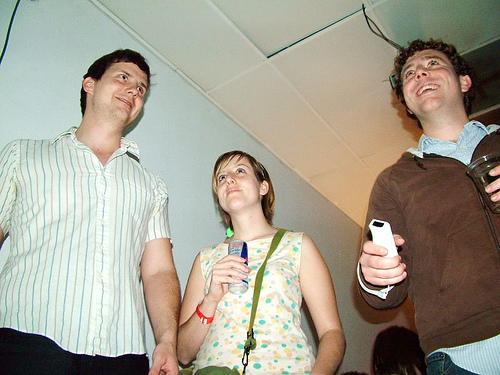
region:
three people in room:
[34, 15, 468, 365]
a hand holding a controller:
[359, 245, 411, 286]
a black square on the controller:
[374, 215, 381, 225]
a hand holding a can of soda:
[211, 257, 248, 285]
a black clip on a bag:
[241, 345, 251, 365]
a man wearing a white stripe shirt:
[11, 22, 167, 359]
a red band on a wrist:
[194, 306, 219, 330]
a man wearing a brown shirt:
[359, 45, 498, 364]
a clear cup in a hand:
[469, 142, 499, 209]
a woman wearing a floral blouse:
[199, 143, 328, 373]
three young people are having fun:
[2, 6, 497, 372]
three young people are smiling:
[6, 21, 489, 277]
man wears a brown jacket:
[349, 23, 499, 365]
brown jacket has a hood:
[352, 123, 499, 357]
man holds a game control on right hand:
[337, 30, 499, 352]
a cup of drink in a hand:
[454, 138, 499, 225]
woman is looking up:
[176, 144, 351, 370]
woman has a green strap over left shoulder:
[173, 150, 347, 374]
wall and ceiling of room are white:
[12, 13, 407, 350]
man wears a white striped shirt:
[6, 33, 190, 374]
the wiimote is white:
[369, 218, 397, 263]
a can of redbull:
[227, 238, 249, 297]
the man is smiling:
[5, 48, 181, 374]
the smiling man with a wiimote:
[359, 40, 499, 374]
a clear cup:
[462, 148, 498, 207]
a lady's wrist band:
[194, 303, 216, 323]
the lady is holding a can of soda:
[177, 149, 349, 374]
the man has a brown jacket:
[359, 39, 498, 374]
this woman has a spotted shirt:
[183, 149, 350, 373]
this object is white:
[366, 218, 397, 262]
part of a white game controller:
[360, 215, 407, 254]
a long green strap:
[238, 223, 290, 358]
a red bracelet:
[192, 300, 217, 325]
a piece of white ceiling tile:
[267, 10, 402, 107]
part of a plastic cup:
[460, 150, 495, 206]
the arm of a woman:
[291, 238, 342, 370]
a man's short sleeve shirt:
[1, 126, 178, 360]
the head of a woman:
[364, 325, 420, 373]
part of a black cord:
[0, 0, 28, 62]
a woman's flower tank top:
[189, 233, 316, 373]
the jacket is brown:
[357, 156, 481, 351]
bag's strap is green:
[249, 235, 277, 324]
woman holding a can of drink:
[179, 153, 300, 345]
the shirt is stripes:
[22, 132, 192, 370]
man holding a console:
[330, 177, 450, 332]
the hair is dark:
[62, 40, 173, 126]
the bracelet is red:
[181, 293, 251, 343]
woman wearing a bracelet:
[159, 157, 246, 352]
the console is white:
[302, 195, 434, 320]